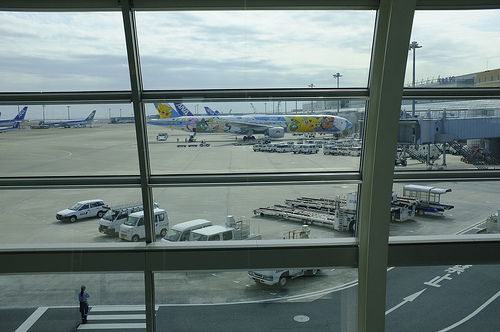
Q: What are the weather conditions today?
A: It is cloudy.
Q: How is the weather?
A: It is cloudy.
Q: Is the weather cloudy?
A: Yes, it is cloudy.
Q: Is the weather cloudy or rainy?
A: It is cloudy.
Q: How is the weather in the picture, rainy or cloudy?
A: It is cloudy.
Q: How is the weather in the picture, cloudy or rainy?
A: It is cloudy.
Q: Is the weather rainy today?
A: No, it is cloudy.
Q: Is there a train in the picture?
A: No, there are no trains.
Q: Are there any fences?
A: No, there are no fences.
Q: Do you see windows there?
A: Yes, there is a window.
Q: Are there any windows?
A: Yes, there is a window.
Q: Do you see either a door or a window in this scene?
A: Yes, there is a window.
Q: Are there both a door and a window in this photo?
A: No, there is a window but no doors.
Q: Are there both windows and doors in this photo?
A: No, there is a window but no doors.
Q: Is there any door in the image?
A: No, there are no doors.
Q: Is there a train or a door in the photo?
A: No, there are no doors or trains.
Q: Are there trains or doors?
A: No, there are no doors or trains.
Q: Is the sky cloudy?
A: Yes, the sky is cloudy.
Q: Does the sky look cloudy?
A: Yes, the sky is cloudy.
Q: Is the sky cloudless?
A: No, the sky is cloudy.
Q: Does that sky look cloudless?
A: No, the sky is cloudy.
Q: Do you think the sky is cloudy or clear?
A: The sky is cloudy.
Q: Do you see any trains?
A: No, there are no trains.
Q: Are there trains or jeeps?
A: No, there are no trains or jeeps.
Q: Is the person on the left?
A: Yes, the person is on the left of the image.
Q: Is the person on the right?
A: No, the person is on the left of the image.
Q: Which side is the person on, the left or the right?
A: The person is on the left of the image.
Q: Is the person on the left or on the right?
A: The person is on the left of the image.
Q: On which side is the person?
A: The person is on the left of the image.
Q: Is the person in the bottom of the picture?
A: Yes, the person is in the bottom of the image.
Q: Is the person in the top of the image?
A: No, the person is in the bottom of the image.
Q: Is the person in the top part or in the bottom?
A: The person is in the bottom of the image.